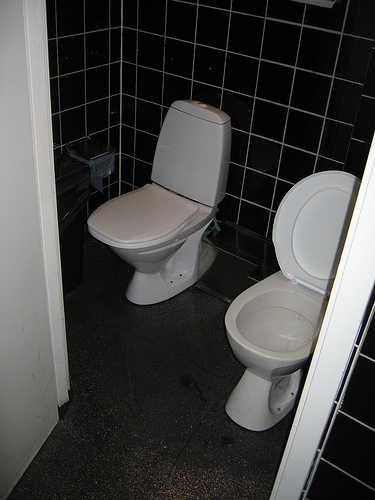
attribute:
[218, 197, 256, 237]
tile — black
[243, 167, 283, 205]
tile — black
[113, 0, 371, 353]
wall — tiled, black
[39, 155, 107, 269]
can — trash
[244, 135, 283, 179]
tile — black